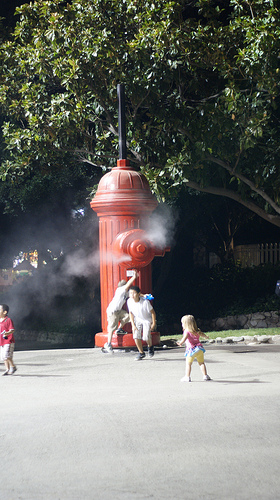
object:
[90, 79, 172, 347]
fire hydrant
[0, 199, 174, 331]
steam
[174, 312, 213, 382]
kid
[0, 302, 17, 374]
kid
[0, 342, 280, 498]
road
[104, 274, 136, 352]
kid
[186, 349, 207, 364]
shorts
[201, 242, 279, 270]
fence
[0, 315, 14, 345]
shirt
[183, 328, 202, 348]
shirt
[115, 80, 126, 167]
pole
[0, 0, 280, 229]
tree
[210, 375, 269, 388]
shadow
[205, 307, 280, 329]
border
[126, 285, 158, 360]
boys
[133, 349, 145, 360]
sneakers